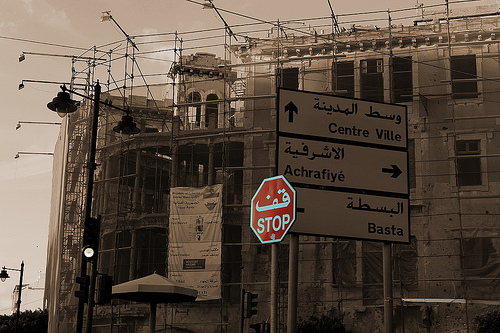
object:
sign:
[275, 86, 409, 248]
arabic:
[278, 90, 406, 142]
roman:
[283, 163, 347, 184]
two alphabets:
[328, 118, 404, 144]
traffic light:
[74, 217, 114, 306]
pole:
[85, 218, 99, 333]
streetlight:
[46, 84, 78, 121]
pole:
[72, 84, 105, 330]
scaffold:
[73, 2, 497, 94]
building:
[15, 17, 500, 333]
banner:
[165, 184, 223, 301]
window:
[446, 49, 486, 104]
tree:
[1, 309, 44, 333]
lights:
[13, 151, 57, 160]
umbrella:
[110, 270, 200, 303]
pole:
[149, 300, 159, 332]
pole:
[268, 246, 276, 331]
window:
[455, 131, 483, 189]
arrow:
[284, 99, 298, 123]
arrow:
[381, 163, 403, 179]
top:
[52, 38, 500, 140]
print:
[255, 190, 289, 234]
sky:
[0, 0, 58, 312]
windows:
[386, 52, 414, 101]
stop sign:
[249, 173, 296, 243]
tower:
[170, 51, 239, 129]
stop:
[256, 213, 290, 233]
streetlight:
[1, 263, 28, 330]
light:
[102, 9, 139, 48]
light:
[15, 47, 101, 66]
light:
[17, 79, 94, 92]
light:
[14, 116, 63, 131]